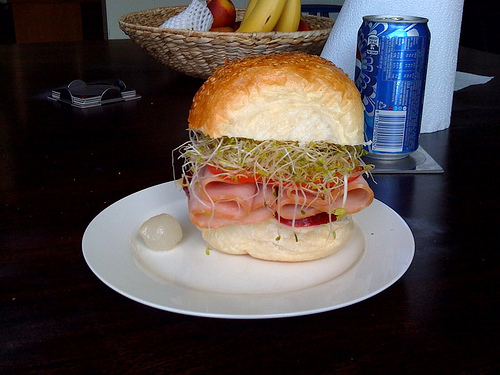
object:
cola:
[352, 13, 430, 163]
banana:
[233, 0, 285, 35]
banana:
[269, 0, 302, 32]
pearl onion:
[136, 213, 183, 248]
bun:
[186, 51, 372, 145]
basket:
[116, 5, 336, 79]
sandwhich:
[170, 49, 377, 264]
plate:
[80, 175, 414, 321]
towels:
[317, 0, 464, 136]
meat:
[275, 173, 375, 221]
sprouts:
[333, 175, 348, 221]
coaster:
[361, 142, 446, 176]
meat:
[185, 170, 279, 229]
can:
[350, 13, 430, 161]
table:
[0, 0, 499, 374]